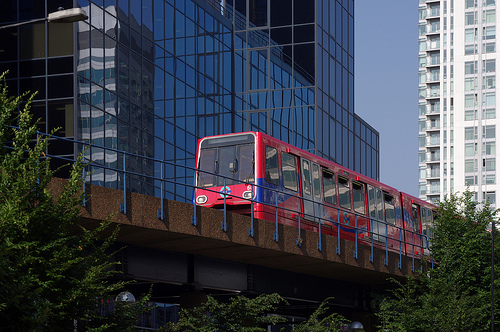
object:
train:
[186, 128, 500, 273]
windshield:
[196, 134, 255, 190]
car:
[189, 130, 406, 260]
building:
[413, 1, 499, 239]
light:
[45, 6, 89, 23]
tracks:
[0, 167, 500, 295]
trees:
[375, 189, 499, 332]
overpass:
[0, 125, 499, 294]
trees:
[163, 287, 289, 332]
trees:
[1, 65, 165, 332]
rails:
[0, 119, 499, 283]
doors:
[300, 156, 325, 224]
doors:
[366, 183, 387, 243]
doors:
[420, 205, 435, 257]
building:
[1, 1, 390, 331]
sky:
[355, 1, 419, 199]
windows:
[266, 144, 281, 186]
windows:
[282, 151, 299, 191]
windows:
[322, 167, 337, 205]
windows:
[338, 174, 352, 211]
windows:
[352, 179, 366, 214]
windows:
[383, 190, 396, 225]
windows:
[411, 202, 420, 233]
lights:
[242, 191, 254, 200]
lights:
[196, 195, 208, 205]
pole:
[44, 16, 50, 175]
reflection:
[74, 0, 153, 198]